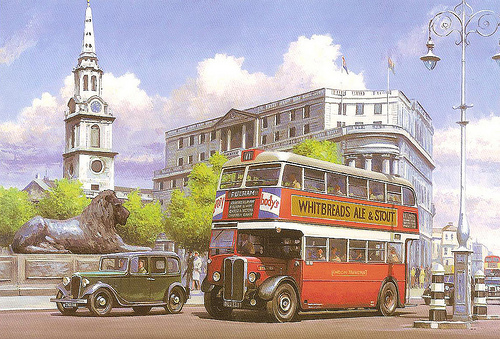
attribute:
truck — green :
[50, 246, 187, 316]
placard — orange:
[282, 183, 408, 236]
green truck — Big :
[54, 248, 191, 316]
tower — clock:
[56, 12, 130, 189]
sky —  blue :
[167, 10, 491, 91]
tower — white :
[69, 9, 112, 196]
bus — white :
[206, 108, 450, 329]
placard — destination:
[226, 193, 260, 219]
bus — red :
[202, 145, 419, 318]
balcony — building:
[164, 88, 434, 140]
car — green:
[46, 244, 190, 318]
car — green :
[61, 232, 208, 331]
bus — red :
[193, 143, 430, 325]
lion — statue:
[3, 187, 136, 260]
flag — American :
[384, 50, 398, 89]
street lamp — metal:
[420, 1, 498, 321]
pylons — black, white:
[423, 257, 450, 324]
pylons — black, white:
[468, 262, 488, 322]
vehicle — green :
[66, 231, 187, 332]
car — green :
[49, 250, 189, 315]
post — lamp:
[450, 2, 485, 323]